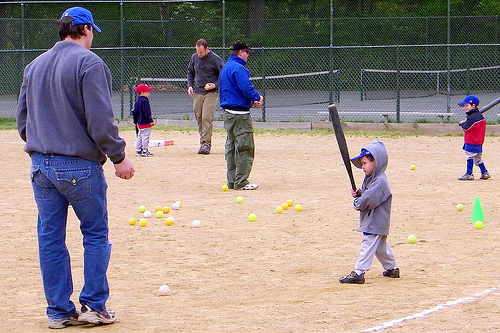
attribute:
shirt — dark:
[16, 34, 142, 177]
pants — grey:
[222, 109, 256, 185]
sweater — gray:
[182, 55, 219, 91]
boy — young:
[452, 92, 487, 184]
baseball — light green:
[406, 233, 416, 243]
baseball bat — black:
[327, 101, 357, 191]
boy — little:
[336, 136, 406, 291]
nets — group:
[128, 68, 499, 135]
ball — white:
[245, 207, 258, 223]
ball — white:
[401, 232, 417, 247]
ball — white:
[155, 274, 167, 305]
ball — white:
[124, 216, 139, 228]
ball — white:
[229, 191, 247, 207]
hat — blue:
[452, 90, 484, 113]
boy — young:
[346, 140, 402, 287]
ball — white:
[191, 220, 202, 227]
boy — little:
[438, 87, 499, 192]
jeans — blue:
[25, 156, 113, 313]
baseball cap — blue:
[56, 5, 105, 38]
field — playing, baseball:
[3, 126, 491, 332]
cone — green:
[454, 192, 486, 230]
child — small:
[332, 107, 405, 292]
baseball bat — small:
[328, 101, 359, 193]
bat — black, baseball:
[325, 104, 357, 196]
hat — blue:
[78, 0, 130, 47]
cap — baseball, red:
[445, 86, 497, 124]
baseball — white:
[157, 283, 169, 297]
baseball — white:
[189, 217, 200, 227]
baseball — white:
[170, 200, 179, 210]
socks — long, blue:
[461, 153, 491, 180]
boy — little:
[119, 76, 162, 160]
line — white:
[364, 280, 484, 331]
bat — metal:
[319, 99, 359, 203]